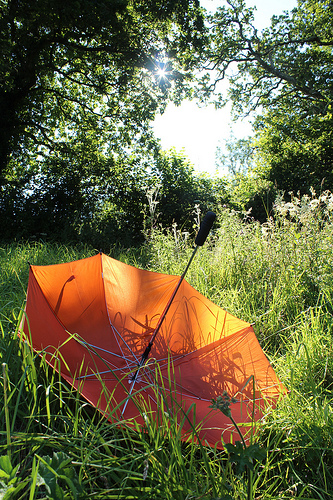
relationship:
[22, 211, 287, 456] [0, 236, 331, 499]
umbrella laying in grass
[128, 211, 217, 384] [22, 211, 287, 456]
handle for umbrella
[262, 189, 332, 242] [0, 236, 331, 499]
weeds growing in grass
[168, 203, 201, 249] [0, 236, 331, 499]
weeds growing in grass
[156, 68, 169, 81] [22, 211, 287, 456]
sun shining on umbrella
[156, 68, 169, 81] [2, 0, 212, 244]
sun shining through trees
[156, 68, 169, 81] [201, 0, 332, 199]
sun shining through trees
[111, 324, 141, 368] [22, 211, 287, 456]
support wire for umbrella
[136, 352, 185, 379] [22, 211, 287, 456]
support wire for umbrella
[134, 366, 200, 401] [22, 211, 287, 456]
support wire for umbrella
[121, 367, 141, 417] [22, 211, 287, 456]
support wire for umbrella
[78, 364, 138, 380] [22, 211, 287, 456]
support wire for umbrella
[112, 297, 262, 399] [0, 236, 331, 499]
silhouette of grass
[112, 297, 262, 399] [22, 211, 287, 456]
silhouette on umbrella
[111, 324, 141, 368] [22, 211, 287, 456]
support wire on underside of umbrella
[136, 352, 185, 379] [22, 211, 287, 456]
support wire on underside of umbrella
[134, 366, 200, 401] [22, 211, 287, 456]
support wire on underside of umbrella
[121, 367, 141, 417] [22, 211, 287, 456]
support wire on underside of umbrella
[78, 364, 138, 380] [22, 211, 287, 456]
support wire on underside of umbrella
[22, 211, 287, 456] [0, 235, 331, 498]
umbrella laying in field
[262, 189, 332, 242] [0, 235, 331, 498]
weeds growing in field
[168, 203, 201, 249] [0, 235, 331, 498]
weeds growing in field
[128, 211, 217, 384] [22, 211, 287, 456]
handle of umbrella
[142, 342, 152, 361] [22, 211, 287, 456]
plastic holds open umbrella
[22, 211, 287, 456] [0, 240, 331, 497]
umbrella sitting on field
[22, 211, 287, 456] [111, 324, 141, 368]
umbrella has support wire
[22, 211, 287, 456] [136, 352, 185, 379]
umbrella has support wire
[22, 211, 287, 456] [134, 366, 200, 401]
umbrella has support wire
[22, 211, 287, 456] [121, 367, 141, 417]
umbrella has support wire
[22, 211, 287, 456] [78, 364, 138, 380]
umbrella has support wire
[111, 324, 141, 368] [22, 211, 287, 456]
support wire on umbrella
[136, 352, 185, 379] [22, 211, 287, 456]
support wire on umbrella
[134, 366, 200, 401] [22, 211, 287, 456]
support wire on umbrella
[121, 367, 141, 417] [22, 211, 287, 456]
support wire on umbrella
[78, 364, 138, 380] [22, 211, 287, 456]
support wire on umbrella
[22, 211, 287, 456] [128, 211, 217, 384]
umbrella has handle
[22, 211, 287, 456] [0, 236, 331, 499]
umbrella lying in grass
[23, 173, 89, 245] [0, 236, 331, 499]
tree next to grass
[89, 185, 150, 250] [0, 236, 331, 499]
tree next to grass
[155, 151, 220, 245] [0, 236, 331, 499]
tree next to grass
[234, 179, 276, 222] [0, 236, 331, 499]
tree next to grass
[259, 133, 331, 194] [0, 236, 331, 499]
tree next to grass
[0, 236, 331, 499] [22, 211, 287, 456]
grass covering umbrella